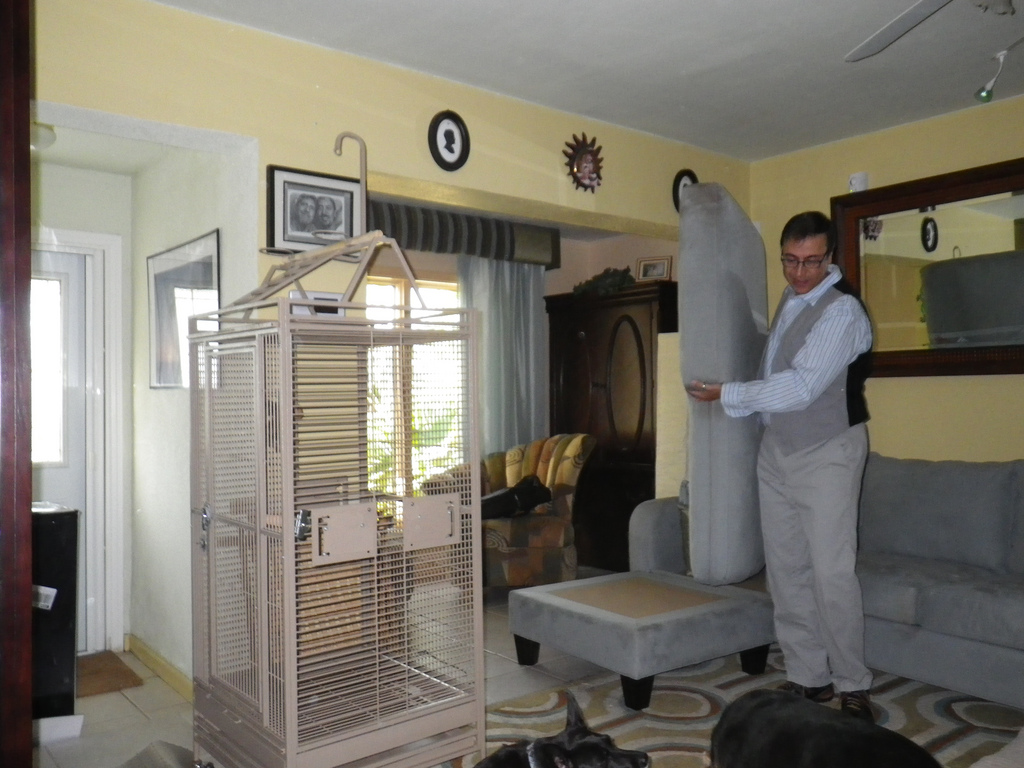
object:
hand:
[685, 379, 721, 401]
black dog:
[707, 681, 939, 768]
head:
[443, 129, 456, 144]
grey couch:
[624, 454, 1024, 706]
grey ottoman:
[507, 571, 775, 710]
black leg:
[740, 645, 770, 675]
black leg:
[621, 675, 654, 710]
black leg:
[514, 634, 541, 665]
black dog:
[469, 690, 658, 768]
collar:
[523, 741, 550, 767]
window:
[28, 276, 64, 464]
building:
[0, 0, 1022, 768]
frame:
[427, 110, 470, 171]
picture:
[284, 181, 353, 246]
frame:
[266, 164, 368, 263]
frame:
[145, 229, 224, 390]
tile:
[120, 677, 188, 718]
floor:
[28, 649, 190, 767]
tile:
[142, 701, 194, 731]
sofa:
[627, 451, 1024, 707]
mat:
[76, 647, 145, 695]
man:
[684, 211, 879, 718]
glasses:
[781, 255, 820, 269]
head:
[444, 129, 457, 154]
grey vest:
[755, 284, 853, 457]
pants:
[755, 425, 870, 694]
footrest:
[507, 571, 775, 709]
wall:
[33, 4, 750, 702]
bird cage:
[187, 232, 489, 768]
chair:
[419, 432, 597, 602]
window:
[365, 275, 463, 533]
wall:
[134, 134, 258, 704]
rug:
[480, 638, 1024, 768]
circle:
[621, 675, 656, 710]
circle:
[766, 652, 786, 672]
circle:
[485, 686, 568, 717]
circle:
[644, 741, 712, 768]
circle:
[485, 741, 539, 763]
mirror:
[829, 156, 1024, 377]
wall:
[748, 91, 1024, 466]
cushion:
[679, 181, 762, 586]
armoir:
[542, 266, 677, 571]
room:
[0, 0, 1024, 767]